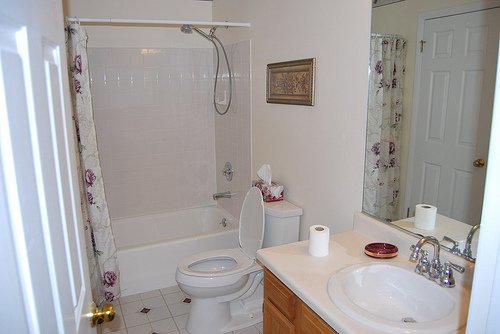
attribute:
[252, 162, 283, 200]
box — decorative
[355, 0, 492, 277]
mirror — large , reflecting 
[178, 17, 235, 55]
shower head — long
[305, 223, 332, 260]
toilet paper — white 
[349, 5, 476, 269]
mirror — rectangular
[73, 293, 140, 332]
handle — gold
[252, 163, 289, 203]
tissue box — red , purple , floral 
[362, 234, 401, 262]
dish — red, gold, soap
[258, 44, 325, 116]
frame — decor , brown , rectangular 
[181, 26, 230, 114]
shower head — silver 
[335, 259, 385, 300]
sink — white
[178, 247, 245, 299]
bowl — ceramic, white, toilet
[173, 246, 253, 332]
toilet bowl — white , porcelain 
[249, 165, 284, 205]
box — white, red, tissue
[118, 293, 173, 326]
floor tile — decorative, bathroom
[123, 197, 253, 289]
bathtub — white, bath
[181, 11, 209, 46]
shower head — silver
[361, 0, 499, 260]
mirror — rectangular 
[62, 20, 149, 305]
shower curtain — patterned , white 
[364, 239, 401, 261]
soap dish — red 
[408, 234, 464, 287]
faucet — silver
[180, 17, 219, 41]
shower wand — hand held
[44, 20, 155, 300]
shower curtain — white , purple , floral 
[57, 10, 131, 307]
shower curtain — flower, print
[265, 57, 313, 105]
framed picture — gold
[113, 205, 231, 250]
white tub — ceramic, huge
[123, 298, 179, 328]
linoleum floor — grey, white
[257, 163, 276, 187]
paper — tissue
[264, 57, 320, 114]
decor — home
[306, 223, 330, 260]
paper — toilet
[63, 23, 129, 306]
curtain — white, flower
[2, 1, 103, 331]
door — white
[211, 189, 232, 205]
faucet — silver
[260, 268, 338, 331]
cupboard — wooden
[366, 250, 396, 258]
stripe — yellow 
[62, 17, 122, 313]
shower curtain — purple 